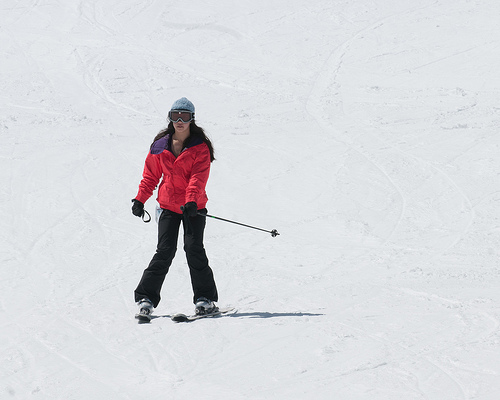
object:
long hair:
[186, 120, 216, 167]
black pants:
[131, 207, 221, 302]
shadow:
[215, 304, 325, 321]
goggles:
[158, 108, 200, 126]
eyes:
[166, 109, 195, 123]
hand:
[177, 199, 199, 216]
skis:
[119, 305, 228, 326]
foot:
[190, 294, 216, 316]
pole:
[179, 205, 281, 238]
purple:
[152, 135, 172, 150]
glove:
[115, 196, 158, 222]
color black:
[124, 120, 226, 305]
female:
[129, 93, 222, 320]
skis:
[173, 306, 238, 322]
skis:
[135, 309, 153, 323]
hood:
[142, 132, 202, 149]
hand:
[124, 200, 150, 217]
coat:
[137, 128, 221, 211]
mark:
[301, 6, 408, 251]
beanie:
[171, 95, 196, 114]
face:
[167, 105, 192, 137]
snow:
[0, 0, 500, 400]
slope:
[0, 0, 494, 396]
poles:
[135, 201, 286, 243]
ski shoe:
[193, 294, 221, 314]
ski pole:
[118, 192, 151, 222]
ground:
[2, 2, 485, 396]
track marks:
[252, 6, 494, 397]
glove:
[179, 202, 199, 220]